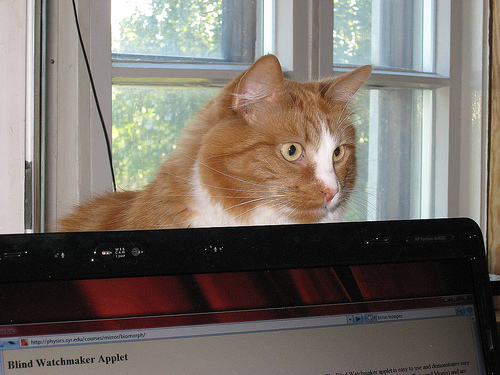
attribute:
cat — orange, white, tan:
[56, 53, 374, 233]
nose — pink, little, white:
[320, 188, 340, 203]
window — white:
[43, 0, 462, 233]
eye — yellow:
[281, 141, 304, 162]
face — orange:
[252, 106, 356, 222]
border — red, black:
[0, 258, 472, 338]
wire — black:
[71, 1, 118, 193]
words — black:
[9, 352, 129, 370]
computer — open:
[0, 217, 497, 374]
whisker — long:
[164, 169, 277, 194]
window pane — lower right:
[338, 90, 434, 221]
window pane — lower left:
[112, 85, 225, 194]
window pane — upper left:
[112, 0, 261, 62]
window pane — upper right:
[334, 0, 438, 72]